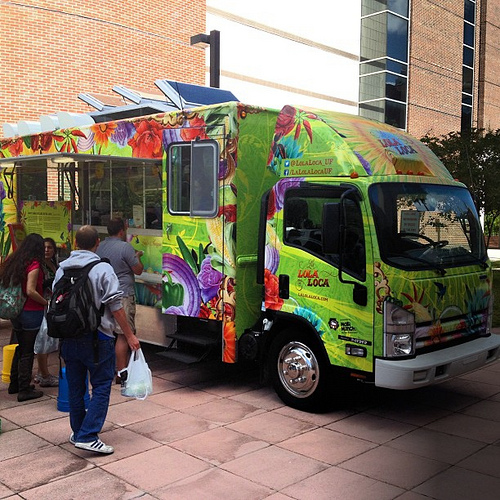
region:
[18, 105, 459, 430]
food truck on road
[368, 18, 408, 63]
window on the building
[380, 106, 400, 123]
window on the building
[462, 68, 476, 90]
window on the building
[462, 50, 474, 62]
window on the building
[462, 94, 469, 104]
window on the building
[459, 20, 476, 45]
window on the building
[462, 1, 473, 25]
window on the building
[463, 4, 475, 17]
window on the building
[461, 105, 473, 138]
window on the building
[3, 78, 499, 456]
Very colorful food truck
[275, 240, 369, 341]
Logos on the door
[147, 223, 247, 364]
Green, yellow, purple and red pictures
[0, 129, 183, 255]
Window where you order food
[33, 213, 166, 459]
Man with a backpack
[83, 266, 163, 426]
Holding a plastic bag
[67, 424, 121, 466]
Stripes on his sneakers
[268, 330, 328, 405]
Very shiny chrome wheel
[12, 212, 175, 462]
People waiting for service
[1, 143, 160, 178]
Awning to protect from sun and rain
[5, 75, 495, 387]
A green food truck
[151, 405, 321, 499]
Beige cement squares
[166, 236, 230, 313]
Design on green food truck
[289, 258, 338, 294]
Logo Lola Loca on green food truck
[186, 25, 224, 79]
Black light post with white light cover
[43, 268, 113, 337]
Man wearing black backpack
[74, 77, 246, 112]
Vents on top of food truck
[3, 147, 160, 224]
Awning on food truck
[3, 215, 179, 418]
People waiting to get food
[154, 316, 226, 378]
Black steps on food truck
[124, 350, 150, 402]
Merchandise purchased by person with back pack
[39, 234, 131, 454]
Person wearing grey hoody and back pack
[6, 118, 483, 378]
A brightly colored truck and trailer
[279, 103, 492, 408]
The cab of the brightly colored truck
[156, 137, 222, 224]
A window on the brightly colored trailer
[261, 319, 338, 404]
Passenger side front tire and wheel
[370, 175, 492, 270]
The windshield of the brightly colored truck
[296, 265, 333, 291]
the words "Lola Loca"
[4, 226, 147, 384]
People in line at the truck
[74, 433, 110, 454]
Shoe worn by person with back pack and shopping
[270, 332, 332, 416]
right front wheel of truck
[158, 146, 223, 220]
window in back of truck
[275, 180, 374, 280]
window on door of truck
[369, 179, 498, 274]
windshield on truck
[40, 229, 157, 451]
man with plastic bag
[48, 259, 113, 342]
black backpack on man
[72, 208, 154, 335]
man at truck window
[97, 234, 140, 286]
grey shirt of man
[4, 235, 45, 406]
woman in pink shirt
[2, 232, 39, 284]
black hair of woman